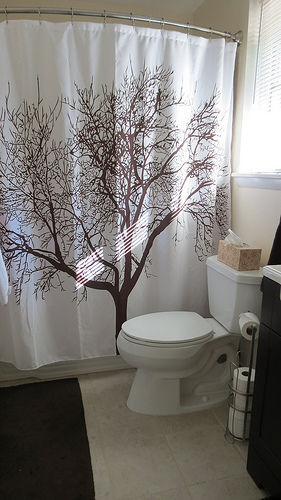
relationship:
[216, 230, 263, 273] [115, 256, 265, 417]
kleenex box on toilet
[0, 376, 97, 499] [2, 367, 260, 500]
rug on floor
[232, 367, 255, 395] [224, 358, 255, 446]
toilet paper in holder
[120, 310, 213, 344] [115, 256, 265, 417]
lid on toilet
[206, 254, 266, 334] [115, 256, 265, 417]
tank on toilet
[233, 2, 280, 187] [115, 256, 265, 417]
window above toilet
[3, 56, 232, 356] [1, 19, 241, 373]
tree on shower curtain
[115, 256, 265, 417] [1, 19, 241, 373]
toilet next to shower curtain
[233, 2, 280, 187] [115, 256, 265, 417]
window over toilet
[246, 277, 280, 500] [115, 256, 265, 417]
cupboard next to toilet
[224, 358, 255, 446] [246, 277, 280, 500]
holder next to cupboard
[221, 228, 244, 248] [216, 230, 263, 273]
tissues in kleenex box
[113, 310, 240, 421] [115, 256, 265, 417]
base of toilet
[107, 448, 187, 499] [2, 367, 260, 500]
tile on floor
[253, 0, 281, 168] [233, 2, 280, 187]
blinds on window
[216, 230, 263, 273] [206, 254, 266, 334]
kleenex box on tank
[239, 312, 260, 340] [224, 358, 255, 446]
toilet paper on holder